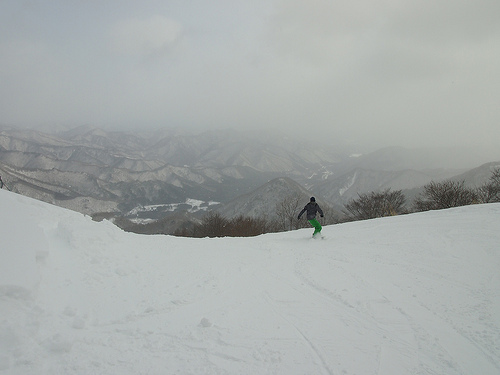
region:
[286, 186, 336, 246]
Man who is snowboarding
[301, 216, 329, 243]
Green snowbooarding pants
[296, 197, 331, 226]
Grey snow jacket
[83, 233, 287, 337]
Snow with tracks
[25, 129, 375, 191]
Mountains in the background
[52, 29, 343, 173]
Cloudy sky with mountains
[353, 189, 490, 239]
Brown trees with no leaves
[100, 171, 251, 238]
Snow in the distance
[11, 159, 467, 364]
Snowy mountain slope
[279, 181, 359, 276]
Snowboarder in green pants and grey jacket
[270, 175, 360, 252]
the man is skiing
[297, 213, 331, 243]
the pants are green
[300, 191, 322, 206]
the man is wearing a black hat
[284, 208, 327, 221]
man is wearing gloves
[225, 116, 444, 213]
fog in the background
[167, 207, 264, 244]
the trees are bare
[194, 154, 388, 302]
man is riding down hill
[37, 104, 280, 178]
mountains in the background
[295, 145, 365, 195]
snow on the mountains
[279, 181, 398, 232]
trees in front of skier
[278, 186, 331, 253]
the person is snowboarding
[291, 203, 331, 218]
the jacket is gray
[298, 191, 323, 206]
the cap is black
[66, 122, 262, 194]
the moutains are brown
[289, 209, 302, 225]
the glove is black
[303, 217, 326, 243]
the person is wearing pants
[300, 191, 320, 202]
the person is wearing a cap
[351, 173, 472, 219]
the bushes are brown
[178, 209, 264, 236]
the bushes are short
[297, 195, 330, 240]
Person is wearing green pants,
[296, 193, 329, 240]
Person is snowboarding.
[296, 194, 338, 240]
Person is wearing a gray jacket.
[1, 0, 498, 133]
The sky is cloudy.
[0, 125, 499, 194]
The mountain range is large.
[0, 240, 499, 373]
Snow is on the ground.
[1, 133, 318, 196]
The mountains are gray.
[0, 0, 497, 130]
The sky is hazy.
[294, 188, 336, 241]
Snowboarder is going downhill.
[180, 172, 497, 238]
The hill has trees and bushes.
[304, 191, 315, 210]
man has dark cap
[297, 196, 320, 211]
man has blue coat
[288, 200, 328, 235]
man has green pants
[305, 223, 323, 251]
man is on snowboard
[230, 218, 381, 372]
white tracks in snow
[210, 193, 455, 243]
bare trees in front of snowboarder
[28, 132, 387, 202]
mountains off in distance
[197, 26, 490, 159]
sky is cloudy and foggy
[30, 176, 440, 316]
man going down hill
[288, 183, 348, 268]
man is riding on snowboard